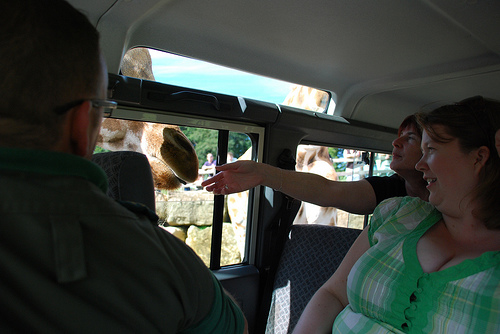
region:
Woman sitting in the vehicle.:
[280, 95, 498, 331]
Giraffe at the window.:
[94, 38, 201, 197]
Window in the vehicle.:
[107, 108, 261, 267]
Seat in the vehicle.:
[262, 220, 367, 332]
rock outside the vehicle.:
[153, 178, 243, 263]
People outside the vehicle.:
[198, 145, 236, 190]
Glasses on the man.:
[1, 2, 128, 184]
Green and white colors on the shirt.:
[327, 110, 498, 329]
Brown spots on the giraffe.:
[95, 41, 212, 196]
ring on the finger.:
[220, 178, 233, 195]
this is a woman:
[298, 90, 494, 326]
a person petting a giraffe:
[85, 56, 410, 236]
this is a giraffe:
[95, 50, 245, 220]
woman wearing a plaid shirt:
[325, 171, 490, 326]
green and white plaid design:
[320, 192, 487, 328]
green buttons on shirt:
[390, 251, 436, 326]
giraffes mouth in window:
[101, 60, 232, 217]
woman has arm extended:
[196, 131, 401, 221]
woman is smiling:
[414, 165, 451, 199]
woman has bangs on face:
[403, 93, 476, 164]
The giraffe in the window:
[120, 110, 290, 218]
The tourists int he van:
[196, 97, 498, 331]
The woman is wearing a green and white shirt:
[311, 192, 496, 330]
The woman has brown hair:
[421, 91, 496, 227]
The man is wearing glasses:
[43, 92, 122, 123]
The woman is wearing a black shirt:
[362, 170, 407, 218]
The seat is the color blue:
[272, 225, 336, 324]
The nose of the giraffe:
[166, 124, 201, 160]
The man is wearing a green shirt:
[6, 142, 252, 332]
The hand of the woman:
[200, 148, 269, 200]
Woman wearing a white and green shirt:
[287, 95, 498, 332]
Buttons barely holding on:
[395, 263, 433, 331]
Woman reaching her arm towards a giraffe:
[200, 108, 429, 214]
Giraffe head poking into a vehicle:
[97, 40, 199, 197]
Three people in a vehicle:
[0, 0, 498, 332]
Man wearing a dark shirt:
[2, 0, 249, 333]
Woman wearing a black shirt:
[200, 108, 429, 218]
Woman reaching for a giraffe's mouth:
[200, 109, 430, 216]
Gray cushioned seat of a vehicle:
[93, 147, 156, 209]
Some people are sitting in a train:
[10, 16, 493, 328]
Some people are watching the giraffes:
[0, 25, 496, 322]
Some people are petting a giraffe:
[20, 41, 487, 331]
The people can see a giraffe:
[15, 31, 485, 328]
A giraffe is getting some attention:
[10, 40, 497, 322]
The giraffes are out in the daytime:
[12, 30, 495, 331]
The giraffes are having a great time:
[15, 31, 487, 319]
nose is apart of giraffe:
[150, 130, 197, 157]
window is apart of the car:
[93, 115, 263, 265]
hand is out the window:
[195, 155, 256, 192]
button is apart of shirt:
[405, 290, 416, 303]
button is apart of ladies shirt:
[399, 319, 407, 331]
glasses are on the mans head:
[55, 95, 120, 115]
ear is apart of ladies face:
[470, 142, 490, 170]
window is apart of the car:
[292, 142, 398, 235]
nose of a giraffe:
[153, 123, 201, 194]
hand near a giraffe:
[198, 156, 258, 197]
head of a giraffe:
[93, 44, 203, 194]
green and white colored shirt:
[323, 187, 495, 332]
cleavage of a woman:
[425, 245, 457, 275]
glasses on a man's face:
[54, 94, 118, 124]